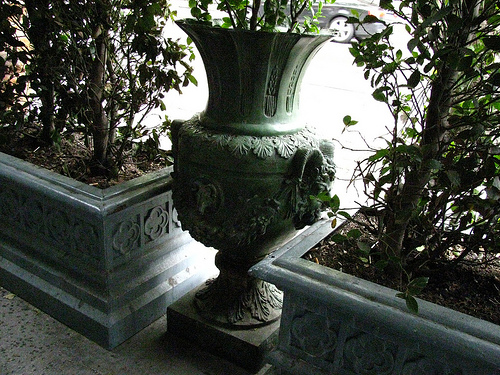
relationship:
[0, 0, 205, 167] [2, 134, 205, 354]
branch in planter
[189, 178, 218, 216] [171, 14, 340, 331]
head on vase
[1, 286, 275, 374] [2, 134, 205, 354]
floor by planter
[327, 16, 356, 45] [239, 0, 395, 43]
wheel on car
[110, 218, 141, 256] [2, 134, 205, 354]
symbol on planter